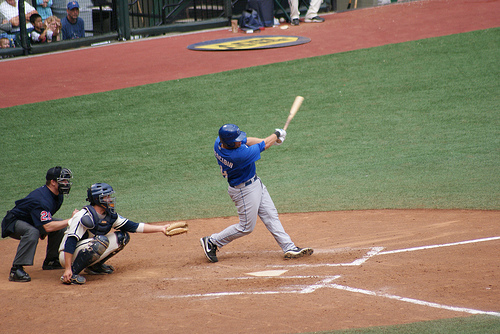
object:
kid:
[26, 11, 62, 46]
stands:
[16, 0, 36, 48]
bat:
[274, 95, 306, 145]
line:
[163, 274, 342, 280]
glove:
[163, 220, 191, 239]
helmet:
[84, 182, 118, 216]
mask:
[98, 191, 118, 219]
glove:
[273, 128, 287, 138]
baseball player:
[198, 122, 318, 264]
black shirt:
[0, 185, 65, 241]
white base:
[239, 265, 289, 278]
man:
[57, 1, 89, 40]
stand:
[0, 0, 397, 59]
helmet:
[217, 123, 248, 146]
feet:
[199, 234, 222, 262]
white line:
[371, 234, 500, 257]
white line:
[324, 282, 500, 319]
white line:
[146, 289, 304, 300]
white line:
[262, 261, 355, 269]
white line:
[351, 245, 388, 266]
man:
[2, 162, 80, 283]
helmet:
[43, 164, 73, 182]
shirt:
[212, 136, 269, 186]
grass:
[1, 26, 500, 226]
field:
[0, 0, 500, 334]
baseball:
[0, 0, 500, 334]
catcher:
[58, 183, 171, 285]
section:
[2, 27, 498, 231]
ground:
[1, 207, 500, 334]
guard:
[55, 165, 72, 198]